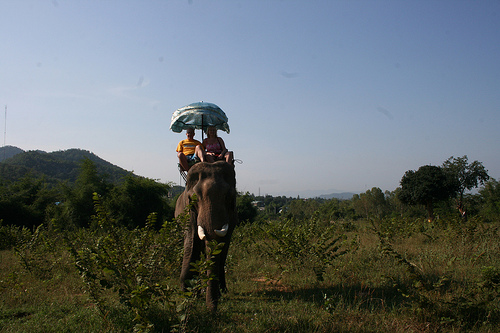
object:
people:
[168, 126, 241, 174]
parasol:
[166, 99, 236, 134]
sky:
[0, 0, 500, 201]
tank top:
[203, 135, 228, 155]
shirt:
[176, 139, 204, 156]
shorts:
[177, 152, 201, 170]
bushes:
[48, 220, 188, 316]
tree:
[394, 156, 489, 226]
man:
[177, 125, 208, 169]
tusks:
[195, 212, 233, 240]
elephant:
[166, 159, 253, 327]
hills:
[0, 144, 179, 227]